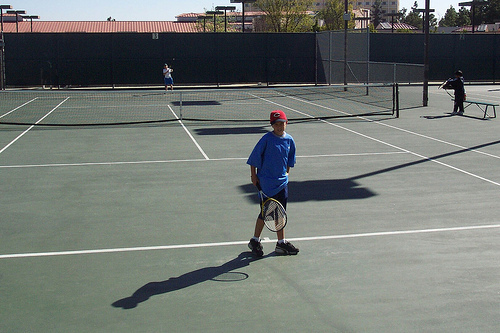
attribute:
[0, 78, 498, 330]
tennis court — green, white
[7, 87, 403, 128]
net — white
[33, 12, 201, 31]
roof top — tiled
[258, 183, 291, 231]
tennis racket — pro kennex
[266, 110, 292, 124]
hat — red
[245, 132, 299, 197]
shirt — blue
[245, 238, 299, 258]
shoes — black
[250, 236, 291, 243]
socks — white